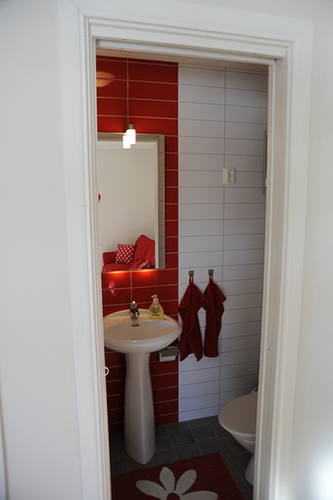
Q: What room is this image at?
A: It is at the bathroom.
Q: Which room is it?
A: It is a bathroom.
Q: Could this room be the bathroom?
A: Yes, it is the bathroom.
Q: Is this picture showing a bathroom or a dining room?
A: It is showing a bathroom.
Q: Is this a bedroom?
A: No, it is a bathroom.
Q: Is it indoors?
A: Yes, it is indoors.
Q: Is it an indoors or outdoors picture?
A: It is indoors.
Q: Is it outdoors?
A: No, it is indoors.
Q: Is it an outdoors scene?
A: No, it is indoors.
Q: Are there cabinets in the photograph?
A: No, there are no cabinets.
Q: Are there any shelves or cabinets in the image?
A: No, there are no cabinets or shelves.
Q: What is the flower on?
A: The flower is on the carpet.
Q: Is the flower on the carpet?
A: Yes, the flower is on the carpet.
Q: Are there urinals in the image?
A: No, there are no urinals.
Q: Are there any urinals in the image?
A: No, there are no urinals.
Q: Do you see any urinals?
A: No, there are no urinals.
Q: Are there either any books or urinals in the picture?
A: No, there are no urinals or books.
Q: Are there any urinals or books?
A: No, there are no urinals or books.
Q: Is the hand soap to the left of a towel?
A: Yes, the hand soap is to the left of a towel.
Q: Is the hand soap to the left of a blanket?
A: No, the hand soap is to the left of a towel.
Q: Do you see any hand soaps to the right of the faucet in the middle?
A: Yes, there is a hand soap to the right of the faucet.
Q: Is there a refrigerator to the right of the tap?
A: No, there is a hand soap to the right of the tap.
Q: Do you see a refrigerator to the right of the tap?
A: No, there is a hand soap to the right of the tap.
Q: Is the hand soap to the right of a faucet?
A: Yes, the hand soap is to the right of a faucet.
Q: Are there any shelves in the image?
A: No, there are no shelves.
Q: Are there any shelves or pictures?
A: No, there are no shelves or pictures.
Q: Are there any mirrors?
A: Yes, there is a mirror.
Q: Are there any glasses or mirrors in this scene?
A: Yes, there is a mirror.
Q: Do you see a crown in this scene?
A: No, there are no crowns.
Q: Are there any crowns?
A: No, there are no crowns.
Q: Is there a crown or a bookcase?
A: No, there are no crowns or bookcases.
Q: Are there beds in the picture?
A: No, there are no beds.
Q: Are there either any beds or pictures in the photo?
A: No, there are no beds or pictures.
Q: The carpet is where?
A: The carpet is on the floor.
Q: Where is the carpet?
A: The carpet is on the floor.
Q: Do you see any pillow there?
A: Yes, there is a pillow.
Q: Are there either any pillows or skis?
A: Yes, there is a pillow.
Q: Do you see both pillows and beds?
A: No, there is a pillow but no beds.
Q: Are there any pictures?
A: No, there are no pictures.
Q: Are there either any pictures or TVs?
A: No, there are no pictures or tvs.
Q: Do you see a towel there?
A: Yes, there is a towel.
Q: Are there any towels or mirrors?
A: Yes, there is a towel.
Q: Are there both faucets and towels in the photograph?
A: Yes, there are both a towel and a faucet.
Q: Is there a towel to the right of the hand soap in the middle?
A: Yes, there is a towel to the right of the hand soap.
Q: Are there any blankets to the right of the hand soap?
A: No, there is a towel to the right of the hand soap.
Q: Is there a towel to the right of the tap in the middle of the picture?
A: Yes, there is a towel to the right of the tap.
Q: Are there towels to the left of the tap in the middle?
A: No, the towel is to the right of the faucet.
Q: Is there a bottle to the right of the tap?
A: No, there is a towel to the right of the tap.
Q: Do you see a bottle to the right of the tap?
A: No, there is a towel to the right of the tap.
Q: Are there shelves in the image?
A: No, there are no shelves.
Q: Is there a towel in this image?
A: Yes, there is a towel.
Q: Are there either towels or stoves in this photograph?
A: Yes, there is a towel.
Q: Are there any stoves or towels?
A: Yes, there is a towel.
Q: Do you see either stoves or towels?
A: Yes, there is a towel.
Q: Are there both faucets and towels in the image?
A: Yes, there are both a towel and a faucet.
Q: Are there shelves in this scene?
A: No, there are no shelves.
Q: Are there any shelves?
A: No, there are no shelves.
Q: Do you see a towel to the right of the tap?
A: Yes, there is a towel to the right of the tap.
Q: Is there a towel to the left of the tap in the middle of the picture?
A: No, the towel is to the right of the tap.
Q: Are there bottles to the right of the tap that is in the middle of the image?
A: No, there is a towel to the right of the faucet.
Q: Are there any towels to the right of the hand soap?
A: Yes, there is a towel to the right of the hand soap.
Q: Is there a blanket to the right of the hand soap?
A: No, there is a towel to the right of the hand soap.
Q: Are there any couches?
A: Yes, there is a couch.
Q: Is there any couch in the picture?
A: Yes, there is a couch.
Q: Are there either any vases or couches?
A: Yes, there is a couch.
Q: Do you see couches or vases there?
A: Yes, there is a couch.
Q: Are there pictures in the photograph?
A: No, there are no pictures.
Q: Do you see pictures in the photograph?
A: No, there are no pictures.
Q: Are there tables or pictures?
A: No, there are no pictures or tables.